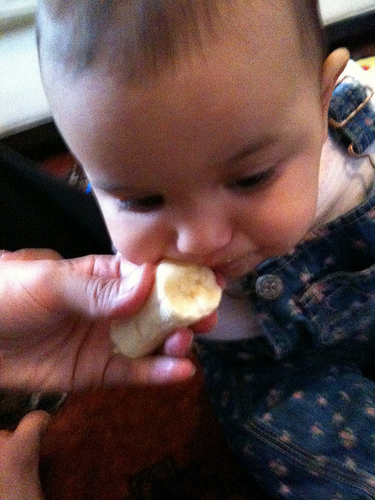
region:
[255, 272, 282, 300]
baby's overall button has fleur de lis on it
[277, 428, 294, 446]
baby's denim overalls have pink flowers on them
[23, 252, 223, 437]
person feeding baby has unpolished fingernails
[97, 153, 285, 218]
baby's eyes look away from banana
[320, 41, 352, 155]
top of baby's ear tilts outward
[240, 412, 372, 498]
baby's overalls have triple seaming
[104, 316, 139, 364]
banana end was cut with a knife, not broken off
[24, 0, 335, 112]
baby's hair is new & sparse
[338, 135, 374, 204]
only the bottom part of baby's overall strap buckle has shadow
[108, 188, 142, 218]
baby has long, curly eyelashes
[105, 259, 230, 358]
banana next to baby's mouth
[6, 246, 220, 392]
hand holding banana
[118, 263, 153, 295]
fingernail on thumb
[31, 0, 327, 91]
hair on baby's head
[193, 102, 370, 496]
baby wearing blue overalls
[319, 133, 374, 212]
white shirt under the overalls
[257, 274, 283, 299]
button on the overalls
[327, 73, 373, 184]
strap of overalls under ear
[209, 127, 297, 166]
eyebrow on baby's face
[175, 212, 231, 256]
nose on face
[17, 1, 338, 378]
Female infant eating banana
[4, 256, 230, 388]
Piece of banana in woman's hand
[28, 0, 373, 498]
Infant in denim overalls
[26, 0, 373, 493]
Infant in blue denim being fed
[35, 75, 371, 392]
Infant female being fed banana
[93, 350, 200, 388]
Woman's pinky finger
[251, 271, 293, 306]
Silver button on denim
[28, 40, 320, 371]
Baby girl eating banana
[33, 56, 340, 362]
Baby girl being fed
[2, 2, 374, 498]
baby eating a banana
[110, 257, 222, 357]
a piece of ripe banana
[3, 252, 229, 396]
hand belonging to adult feeding baby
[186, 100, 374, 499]
baby wearing blue flowered overalls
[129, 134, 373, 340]
a white shirt under the overalls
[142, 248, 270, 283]
the mouth of a baby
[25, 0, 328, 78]
the baby has very fine hair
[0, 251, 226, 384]
hand holding a banana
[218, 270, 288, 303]
the overalls have a metal clasp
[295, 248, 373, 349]
a pocket on the front of the overalls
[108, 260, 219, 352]
piece of mushy yellow banana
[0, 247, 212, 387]
hand with thumb and fingers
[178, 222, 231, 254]
small baby nose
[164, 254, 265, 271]
small baby mouth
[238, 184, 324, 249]
small baby cheek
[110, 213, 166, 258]
small baby cheek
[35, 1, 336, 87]
wispy brown baby hair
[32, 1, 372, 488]
small baby girl eating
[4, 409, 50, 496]
thick thumb with thumbnail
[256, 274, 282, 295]
metal round button with thread holes